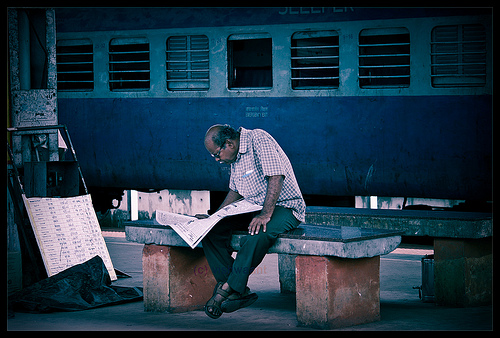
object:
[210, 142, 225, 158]
glasses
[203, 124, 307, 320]
man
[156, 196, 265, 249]
paper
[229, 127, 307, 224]
shirt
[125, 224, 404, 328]
bench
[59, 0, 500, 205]
train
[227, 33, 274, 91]
window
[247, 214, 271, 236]
hand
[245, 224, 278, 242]
knee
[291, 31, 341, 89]
window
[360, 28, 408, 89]
window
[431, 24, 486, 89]
window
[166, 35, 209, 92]
window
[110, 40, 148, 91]
window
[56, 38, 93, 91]
window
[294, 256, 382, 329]
leg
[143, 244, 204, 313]
leg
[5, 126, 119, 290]
stand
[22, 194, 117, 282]
paper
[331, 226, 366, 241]
reflection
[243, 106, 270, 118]
mark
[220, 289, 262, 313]
sandals